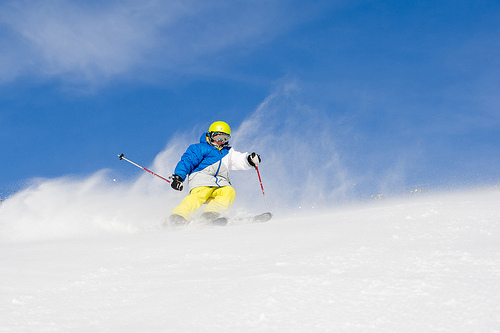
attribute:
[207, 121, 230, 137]
helmet — yellow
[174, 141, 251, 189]
jacket — white, blue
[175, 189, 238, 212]
pants — yellow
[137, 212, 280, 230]
snow skis — sturdy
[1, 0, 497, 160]
sky — blue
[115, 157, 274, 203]
ski poles — red, white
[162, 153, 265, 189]
gloves — black, warm